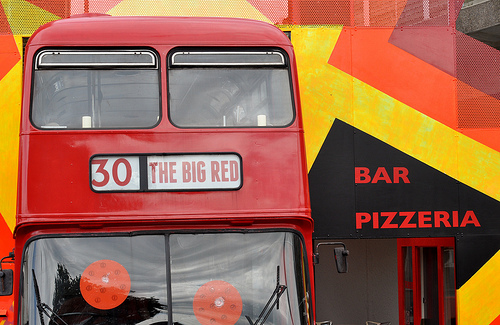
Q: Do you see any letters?
A: Yes, there are letters.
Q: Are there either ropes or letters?
A: Yes, there are letters.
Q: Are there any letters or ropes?
A: Yes, there are letters.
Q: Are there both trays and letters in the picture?
A: No, there are letters but no trays.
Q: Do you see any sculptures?
A: No, there are no sculptures.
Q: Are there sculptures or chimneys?
A: No, there are no sculptures or chimneys.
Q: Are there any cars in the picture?
A: No, there are no cars.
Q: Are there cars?
A: No, there are no cars.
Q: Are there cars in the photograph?
A: No, there are no cars.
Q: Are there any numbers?
A: Yes, there are numbers.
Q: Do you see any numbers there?
A: Yes, there are numbers.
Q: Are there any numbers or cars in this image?
A: Yes, there are numbers.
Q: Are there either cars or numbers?
A: Yes, there are numbers.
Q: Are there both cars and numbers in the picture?
A: No, there are numbers but no cars.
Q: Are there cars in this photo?
A: No, there are no cars.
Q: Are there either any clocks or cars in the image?
A: No, there are no cars or clocks.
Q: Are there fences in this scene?
A: No, there are no fences.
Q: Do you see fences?
A: No, there are no fences.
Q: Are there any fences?
A: No, there are no fences.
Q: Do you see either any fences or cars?
A: No, there are no fences or cars.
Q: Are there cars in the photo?
A: No, there are no cars.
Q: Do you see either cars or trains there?
A: No, there are no cars or trains.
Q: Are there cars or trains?
A: No, there are no cars or trains.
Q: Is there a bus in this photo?
A: Yes, there is a bus.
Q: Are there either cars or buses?
A: Yes, there is a bus.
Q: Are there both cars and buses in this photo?
A: No, there is a bus but no cars.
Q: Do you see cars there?
A: No, there are no cars.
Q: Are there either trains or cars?
A: No, there are no cars or trains.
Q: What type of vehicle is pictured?
A: The vehicle is a bus.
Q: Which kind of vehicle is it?
A: The vehicle is a bus.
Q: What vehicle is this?
A: This is a bus.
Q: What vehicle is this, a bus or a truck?
A: This is a bus.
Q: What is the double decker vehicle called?
A: The vehicle is a bus.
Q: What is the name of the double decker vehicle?
A: The vehicle is a bus.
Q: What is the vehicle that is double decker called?
A: The vehicle is a bus.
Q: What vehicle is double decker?
A: The vehicle is a bus.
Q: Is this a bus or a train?
A: This is a bus.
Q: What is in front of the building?
A: The bus is in front of the building.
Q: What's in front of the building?
A: The bus is in front of the building.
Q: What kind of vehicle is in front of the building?
A: The vehicle is a bus.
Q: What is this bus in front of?
A: The bus is in front of the building.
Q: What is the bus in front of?
A: The bus is in front of the building.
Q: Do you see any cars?
A: No, there are no cars.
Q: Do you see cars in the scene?
A: No, there are no cars.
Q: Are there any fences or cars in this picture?
A: No, there are no cars or fences.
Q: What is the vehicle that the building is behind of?
A: The vehicle is a bus.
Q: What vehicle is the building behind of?
A: The building is behind the bus.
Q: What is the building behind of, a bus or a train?
A: The building is behind a bus.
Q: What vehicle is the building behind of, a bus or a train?
A: The building is behind a bus.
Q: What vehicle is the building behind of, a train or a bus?
A: The building is behind a bus.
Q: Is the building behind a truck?
A: No, the building is behind the bus.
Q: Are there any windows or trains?
A: Yes, there is a window.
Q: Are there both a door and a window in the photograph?
A: Yes, there are both a window and a door.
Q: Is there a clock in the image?
A: No, there are no clocks.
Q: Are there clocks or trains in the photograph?
A: No, there are no clocks or trains.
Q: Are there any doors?
A: Yes, there is a door.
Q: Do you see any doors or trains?
A: Yes, there is a door.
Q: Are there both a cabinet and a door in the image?
A: No, there is a door but no cabinets.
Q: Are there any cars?
A: No, there are no cars.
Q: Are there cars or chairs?
A: No, there are no cars or chairs.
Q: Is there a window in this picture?
A: Yes, there are windows.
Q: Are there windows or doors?
A: Yes, there are windows.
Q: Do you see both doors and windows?
A: Yes, there are both windows and a door.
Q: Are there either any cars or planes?
A: No, there are no cars or planes.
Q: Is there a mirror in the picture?
A: Yes, there is a mirror.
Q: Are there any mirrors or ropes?
A: Yes, there is a mirror.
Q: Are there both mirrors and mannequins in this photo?
A: No, there is a mirror but no mannequins.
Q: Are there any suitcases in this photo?
A: No, there are no suitcases.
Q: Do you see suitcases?
A: No, there are no suitcases.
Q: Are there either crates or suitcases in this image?
A: No, there are no suitcases or crates.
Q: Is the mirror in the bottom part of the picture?
A: Yes, the mirror is in the bottom of the image.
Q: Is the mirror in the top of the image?
A: No, the mirror is in the bottom of the image.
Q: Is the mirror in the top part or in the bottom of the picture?
A: The mirror is in the bottom of the image.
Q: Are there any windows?
A: Yes, there is a window.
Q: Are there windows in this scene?
A: Yes, there is a window.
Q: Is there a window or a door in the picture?
A: Yes, there is a window.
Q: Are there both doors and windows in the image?
A: Yes, there are both a window and a door.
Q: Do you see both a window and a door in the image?
A: Yes, there are both a window and a door.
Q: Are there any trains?
A: No, there are no trains.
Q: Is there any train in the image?
A: No, there are no trains.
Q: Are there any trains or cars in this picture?
A: No, there are no trains or cars.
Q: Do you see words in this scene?
A: Yes, there are words.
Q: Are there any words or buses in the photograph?
A: Yes, there are words.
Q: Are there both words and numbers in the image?
A: Yes, there are both words and numbers.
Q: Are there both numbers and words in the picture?
A: Yes, there are both words and numbers.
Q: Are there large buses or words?
A: Yes, there are large words.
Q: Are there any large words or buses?
A: Yes, there are large words.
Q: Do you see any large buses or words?
A: Yes, there are large words.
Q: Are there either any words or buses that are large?
A: Yes, the words are large.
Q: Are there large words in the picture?
A: Yes, there are large words.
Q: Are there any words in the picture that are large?
A: Yes, there are words that are large.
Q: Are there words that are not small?
A: Yes, there are large words.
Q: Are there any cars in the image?
A: No, there are no cars.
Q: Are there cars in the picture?
A: No, there are no cars.